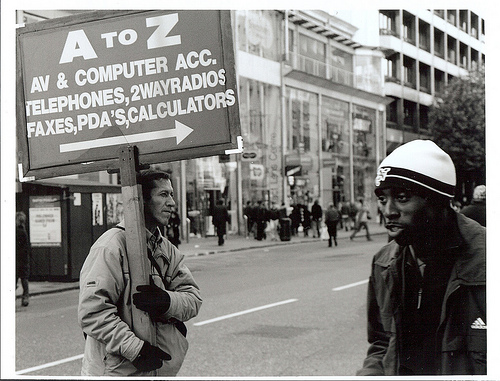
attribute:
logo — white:
[469, 315, 486, 333]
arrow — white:
[49, 124, 208, 152]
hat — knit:
[378, 119, 465, 204]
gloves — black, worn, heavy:
[127, 281, 172, 374]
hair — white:
[468, 182, 484, 201]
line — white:
[203, 288, 299, 333]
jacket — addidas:
[375, 244, 487, 343]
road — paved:
[199, 263, 319, 375]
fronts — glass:
[237, 33, 388, 158]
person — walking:
[354, 208, 373, 242]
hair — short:
[136, 165, 166, 202]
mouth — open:
[385, 224, 402, 241]